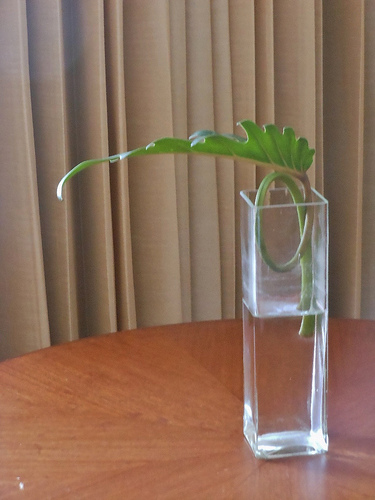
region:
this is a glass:
[237, 208, 329, 410]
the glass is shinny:
[260, 264, 305, 383]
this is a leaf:
[158, 126, 322, 183]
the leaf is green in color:
[253, 128, 294, 156]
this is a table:
[58, 368, 170, 466]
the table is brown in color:
[50, 372, 125, 407]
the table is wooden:
[54, 361, 156, 437]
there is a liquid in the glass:
[265, 347, 322, 407]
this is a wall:
[22, 47, 159, 132]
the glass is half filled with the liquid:
[244, 307, 332, 457]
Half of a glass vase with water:
[241, 302, 330, 455]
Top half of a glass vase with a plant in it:
[239, 185, 330, 313]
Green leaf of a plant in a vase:
[36, 113, 327, 203]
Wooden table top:
[40, 323, 225, 498]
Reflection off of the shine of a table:
[1, 467, 37, 498]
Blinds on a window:
[4, 3, 82, 338]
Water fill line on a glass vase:
[239, 295, 329, 329]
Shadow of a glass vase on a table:
[257, 415, 371, 468]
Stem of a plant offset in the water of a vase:
[295, 295, 315, 340]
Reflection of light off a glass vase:
[308, 423, 328, 454]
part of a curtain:
[252, 75, 293, 104]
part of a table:
[151, 421, 202, 469]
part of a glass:
[272, 380, 303, 429]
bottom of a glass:
[265, 430, 310, 465]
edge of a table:
[19, 353, 41, 365]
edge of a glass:
[246, 370, 262, 421]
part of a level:
[272, 316, 303, 333]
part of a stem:
[295, 277, 315, 295]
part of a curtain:
[149, 278, 181, 313]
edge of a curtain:
[28, 288, 62, 330]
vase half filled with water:
[237, 186, 335, 465]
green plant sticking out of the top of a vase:
[47, 112, 368, 335]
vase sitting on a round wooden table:
[0, 306, 372, 499]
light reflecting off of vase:
[303, 417, 336, 455]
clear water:
[235, 299, 331, 462]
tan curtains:
[0, 0, 373, 361]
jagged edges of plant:
[225, 117, 317, 172]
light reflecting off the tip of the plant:
[52, 179, 69, 206]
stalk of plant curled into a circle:
[252, 164, 319, 283]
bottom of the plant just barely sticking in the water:
[286, 290, 318, 340]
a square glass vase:
[235, 183, 331, 461]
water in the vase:
[238, 292, 332, 464]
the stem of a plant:
[252, 173, 324, 338]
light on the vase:
[301, 422, 331, 457]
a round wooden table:
[0, 312, 371, 494]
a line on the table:
[155, 322, 238, 412]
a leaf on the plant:
[51, 115, 313, 205]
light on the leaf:
[52, 178, 69, 205]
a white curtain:
[0, 0, 374, 363]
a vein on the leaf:
[269, 129, 292, 166]